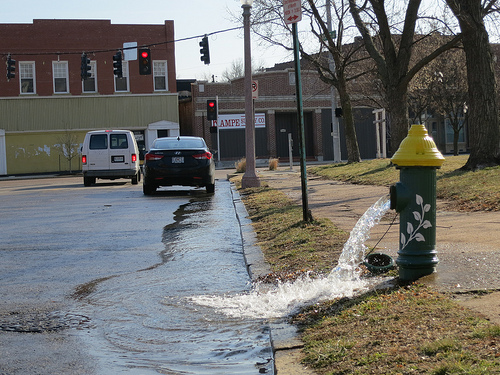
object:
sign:
[283, 4, 302, 23]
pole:
[289, 25, 313, 222]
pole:
[239, 5, 257, 181]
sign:
[252, 80, 261, 99]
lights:
[200, 36, 210, 66]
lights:
[136, 45, 152, 73]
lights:
[109, 48, 126, 79]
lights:
[80, 60, 92, 82]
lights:
[2, 56, 22, 82]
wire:
[10, 13, 181, 69]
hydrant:
[383, 108, 443, 281]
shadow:
[92, 195, 114, 223]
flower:
[398, 191, 432, 258]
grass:
[239, 177, 500, 375]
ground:
[242, 167, 462, 341]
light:
[132, 46, 156, 78]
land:
[24, 141, 447, 311]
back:
[135, 132, 215, 192]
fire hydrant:
[387, 119, 445, 279]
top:
[387, 124, 447, 167]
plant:
[395, 190, 432, 256]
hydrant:
[385, 120, 441, 268]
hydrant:
[384, 117, 447, 274]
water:
[217, 232, 387, 318]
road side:
[179, 186, 255, 354]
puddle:
[107, 212, 272, 353]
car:
[136, 132, 214, 192]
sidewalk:
[262, 115, 452, 295]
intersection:
[17, 147, 258, 195]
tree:
[365, 9, 431, 153]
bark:
[459, 0, 498, 173]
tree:
[429, 0, 499, 165]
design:
[398, 189, 432, 251]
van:
[81, 127, 141, 185]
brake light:
[127, 152, 136, 162]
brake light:
[80, 153, 88, 165]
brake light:
[104, 125, 113, 133]